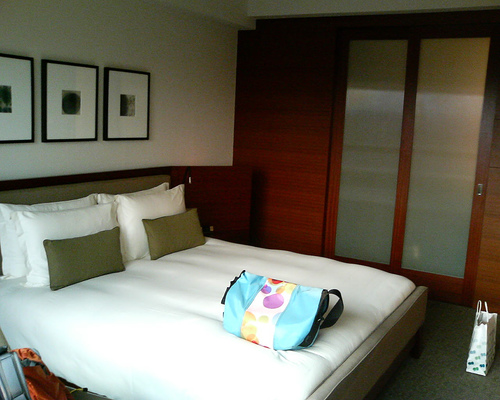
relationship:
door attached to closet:
[313, 40, 476, 297] [246, 28, 498, 304]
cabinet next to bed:
[155, 162, 253, 255] [2, 173, 435, 398]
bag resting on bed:
[218, 265, 346, 352] [2, 173, 435, 398]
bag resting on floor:
[461, 291, 498, 383] [387, 294, 497, 397]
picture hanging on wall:
[95, 53, 169, 156] [1, 0, 238, 180]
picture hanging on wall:
[2, 40, 45, 149] [1, 0, 238, 180]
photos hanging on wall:
[40, 60, 100, 142] [1, 0, 238, 180]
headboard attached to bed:
[0, 173, 170, 277] [2, 173, 435, 398]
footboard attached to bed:
[317, 277, 429, 398] [18, 178, 452, 392]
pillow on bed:
[17, 195, 135, 285] [32, 155, 442, 397]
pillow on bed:
[101, 180, 217, 265] [32, 155, 442, 397]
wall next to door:
[249, 19, 347, 258] [329, 21, 494, 299]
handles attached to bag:
[315, 285, 351, 329] [212, 257, 359, 354]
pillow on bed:
[143, 208, 205, 261] [2, 173, 435, 398]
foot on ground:
[402, 329, 427, 366] [423, 328, 470, 393]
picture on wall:
[103, 66, 151, 142] [1, 5, 228, 187]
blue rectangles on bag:
[472, 350, 484, 369] [462, 295, 497, 380]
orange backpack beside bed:
[13, 346, 64, 398] [2, 173, 435, 398]